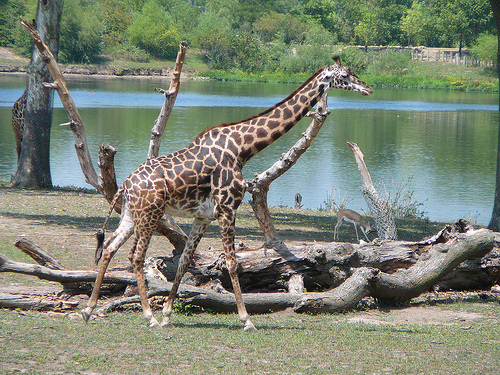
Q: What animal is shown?
A: A giraffe.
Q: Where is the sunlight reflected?
A: Off the water.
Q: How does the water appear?
A: Placid.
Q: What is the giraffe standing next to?
A: Downed logs.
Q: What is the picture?
A: Giraffe.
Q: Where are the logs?
A: By giraffe.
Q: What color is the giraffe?
A: Brown.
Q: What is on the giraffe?
A: Spots.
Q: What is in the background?
A: Trees.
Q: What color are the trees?
A: Green.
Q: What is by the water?
A: Deer.